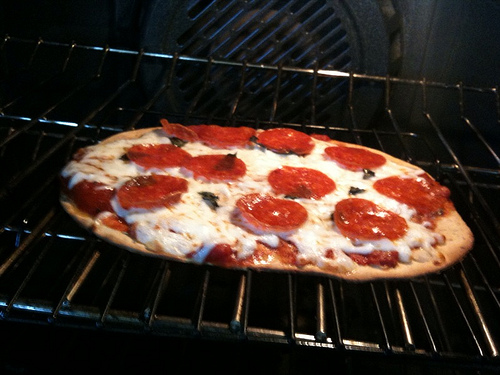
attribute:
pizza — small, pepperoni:
[55, 107, 479, 284]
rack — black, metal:
[0, 32, 496, 366]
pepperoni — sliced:
[115, 170, 190, 212]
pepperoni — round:
[237, 188, 309, 235]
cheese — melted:
[64, 125, 456, 271]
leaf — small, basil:
[200, 190, 221, 210]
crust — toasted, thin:
[58, 120, 475, 282]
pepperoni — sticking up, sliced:
[159, 117, 206, 144]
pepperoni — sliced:
[196, 122, 255, 148]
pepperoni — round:
[125, 143, 194, 170]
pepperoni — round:
[180, 154, 249, 184]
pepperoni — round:
[267, 165, 335, 198]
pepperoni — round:
[258, 125, 314, 156]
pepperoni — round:
[324, 146, 387, 171]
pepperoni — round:
[375, 172, 451, 216]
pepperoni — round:
[118, 173, 190, 209]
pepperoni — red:
[123, 115, 449, 241]